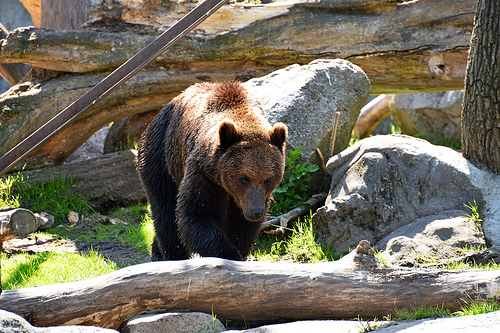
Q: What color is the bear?
A: Brown.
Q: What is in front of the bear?
A: A log.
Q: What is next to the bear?
A: Grass.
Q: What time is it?
A: Afternoon.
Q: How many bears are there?
A: One.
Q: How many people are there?
A: None.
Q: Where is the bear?
A: In a zoo.